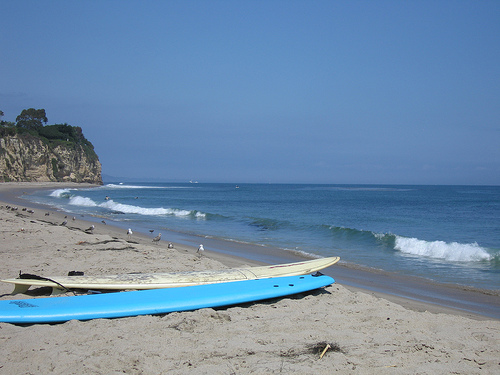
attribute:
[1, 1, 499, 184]
sky — blue, calm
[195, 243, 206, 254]
seagull — white, standing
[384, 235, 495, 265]
waves — cresting, crashing, small, water, active, breaking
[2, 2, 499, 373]
beach — sandy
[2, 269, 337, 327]
surfboard — blue, long, large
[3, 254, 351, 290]
surfboard — white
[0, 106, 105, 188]
cliff — large, big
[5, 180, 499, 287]
ocean — calm, blue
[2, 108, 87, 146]
vegetation — green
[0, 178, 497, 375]
sand — brown